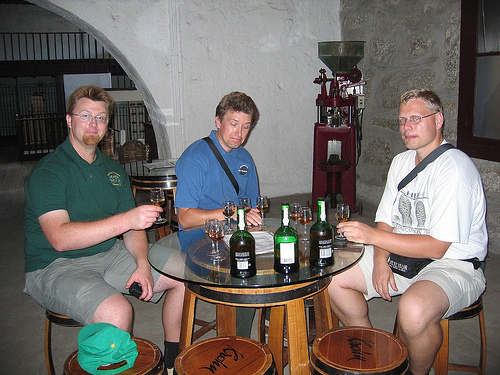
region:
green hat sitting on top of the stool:
[67, 322, 160, 374]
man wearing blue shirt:
[169, 93, 267, 222]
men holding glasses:
[26, 86, 484, 373]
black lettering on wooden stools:
[172, 326, 413, 373]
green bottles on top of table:
[150, 212, 365, 374]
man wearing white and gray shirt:
[329, 92, 489, 373]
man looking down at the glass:
[172, 92, 271, 244]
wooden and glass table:
[149, 206, 366, 373]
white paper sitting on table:
[154, 212, 364, 374]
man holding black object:
[26, 83, 188, 373]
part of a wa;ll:
[241, 17, 276, 63]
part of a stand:
[290, 332, 305, 352]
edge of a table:
[256, 289, 281, 308]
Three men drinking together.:
[20, 80, 486, 345]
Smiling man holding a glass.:
[46, 80, 176, 231]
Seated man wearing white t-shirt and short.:
[364, 85, 492, 330]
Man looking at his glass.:
[175, 90, 275, 221]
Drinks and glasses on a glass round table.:
[146, 210, 366, 290]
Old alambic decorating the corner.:
[306, 35, 361, 220]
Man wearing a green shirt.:
[15, 145, 145, 276]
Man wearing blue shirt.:
[172, 135, 262, 215]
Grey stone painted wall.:
[142, 5, 307, 90]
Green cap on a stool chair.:
[73, 320, 138, 373]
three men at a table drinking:
[27, 69, 484, 344]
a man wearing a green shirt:
[22, 137, 142, 275]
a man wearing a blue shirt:
[170, 91, 264, 250]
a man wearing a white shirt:
[357, 86, 487, 283]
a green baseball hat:
[72, 322, 135, 374]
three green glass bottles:
[230, 199, 335, 277]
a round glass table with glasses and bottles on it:
[149, 216, 366, 289]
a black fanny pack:
[387, 251, 429, 276]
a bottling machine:
[315, 38, 367, 214]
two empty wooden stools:
[177, 329, 406, 374]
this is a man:
[21, 78, 137, 309]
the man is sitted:
[27, 78, 137, 296]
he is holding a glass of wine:
[139, 184, 169, 223]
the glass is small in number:
[147, 188, 169, 206]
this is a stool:
[319, 328, 387, 372]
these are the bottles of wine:
[237, 199, 337, 278]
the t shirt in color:
[62, 168, 102, 216]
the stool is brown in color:
[330, 330, 391, 367]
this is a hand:
[385, 229, 437, 251]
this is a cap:
[65, 320, 127, 370]